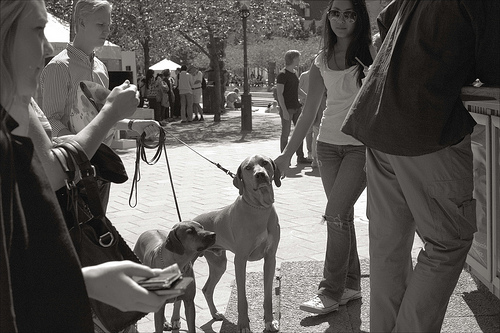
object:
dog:
[172, 154, 284, 332]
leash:
[127, 124, 236, 209]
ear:
[272, 157, 282, 186]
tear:
[322, 214, 351, 226]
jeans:
[314, 139, 372, 304]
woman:
[270, 0, 385, 314]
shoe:
[299, 291, 343, 315]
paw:
[238, 323, 250, 333]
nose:
[252, 171, 267, 178]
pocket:
[418, 176, 475, 240]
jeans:
[362, 133, 475, 332]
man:
[34, 0, 112, 219]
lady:
[0, 0, 95, 333]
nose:
[43, 36, 55, 56]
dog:
[134, 218, 217, 332]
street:
[0, 127, 500, 333]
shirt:
[309, 47, 379, 147]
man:
[336, 0, 499, 333]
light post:
[238, 8, 252, 133]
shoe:
[339, 285, 362, 306]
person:
[173, 63, 194, 123]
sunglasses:
[327, 9, 358, 24]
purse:
[52, 139, 159, 333]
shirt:
[340, 0, 499, 156]